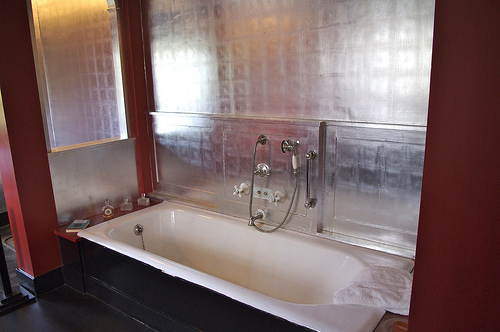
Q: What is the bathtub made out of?
A: Ceramic.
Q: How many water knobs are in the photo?
A: 2.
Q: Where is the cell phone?
A: On the ledge.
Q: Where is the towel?
A: Hanging into the tub.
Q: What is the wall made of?
A: Glass.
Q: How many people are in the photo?
A: 0.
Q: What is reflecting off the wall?
A: Light.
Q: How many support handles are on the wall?
A: 1.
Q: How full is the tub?
A: It is empty.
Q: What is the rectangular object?
A: Bathtub.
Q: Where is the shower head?
A: On the wall behind the tub.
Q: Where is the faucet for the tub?
A: On the wall behind the tub.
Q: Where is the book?
A: On a small shelf near the tub.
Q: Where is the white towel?
A: Lying on the back of the tub.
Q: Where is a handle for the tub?
A: On the wall behind the tub.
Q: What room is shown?
A: Bathroom.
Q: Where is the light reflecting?
A: Wall behind the toilet.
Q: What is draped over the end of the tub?
A: Towel.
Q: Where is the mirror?
A: Wall at the end of the tub.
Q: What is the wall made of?
A: Glass.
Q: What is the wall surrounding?
A: A tub.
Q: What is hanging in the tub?
A: A chain.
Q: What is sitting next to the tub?
A: Bottles.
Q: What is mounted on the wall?
A: Faucet.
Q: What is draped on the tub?
A: A towel.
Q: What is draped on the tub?
A: A towel.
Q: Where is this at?
A: The bathroom.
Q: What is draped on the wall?
A: A shower head.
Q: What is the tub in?
A: An enclosure.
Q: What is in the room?
A: A bathtub.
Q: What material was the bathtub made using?
A: Porcelain.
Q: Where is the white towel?
A: On the edge of the bathtub.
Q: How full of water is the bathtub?
A: Empty.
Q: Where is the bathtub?
A: Bathroom.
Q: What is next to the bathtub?
A: A wall.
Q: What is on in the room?
A: A light.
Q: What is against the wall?
A: Backsplash.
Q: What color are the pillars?
A: Red.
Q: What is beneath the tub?
A: Tile.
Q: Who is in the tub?
A: No one.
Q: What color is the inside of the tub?
A: White.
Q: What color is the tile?
A: Black.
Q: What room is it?
A: Bathroom.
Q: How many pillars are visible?
A: Three.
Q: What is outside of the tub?
A: A towel.